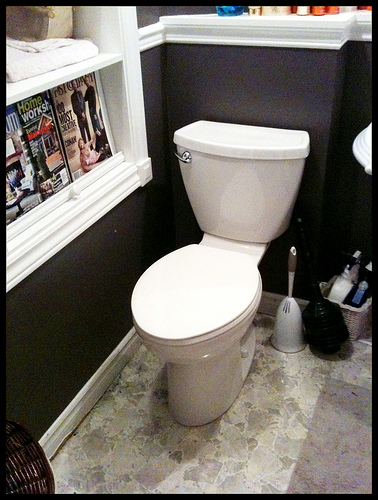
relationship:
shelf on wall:
[2, 18, 156, 201] [114, 1, 216, 172]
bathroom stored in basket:
[316, 240, 374, 342] [321, 265, 366, 341]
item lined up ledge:
[213, 4, 243, 16] [157, 12, 351, 47]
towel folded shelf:
[5, 36, 99, 81] [5, 53, 120, 106]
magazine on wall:
[46, 69, 113, 181] [0, 6, 177, 463]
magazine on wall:
[14, 89, 73, 201] [0, 6, 177, 463]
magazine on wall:
[5, 105, 45, 227] [0, 6, 177, 463]